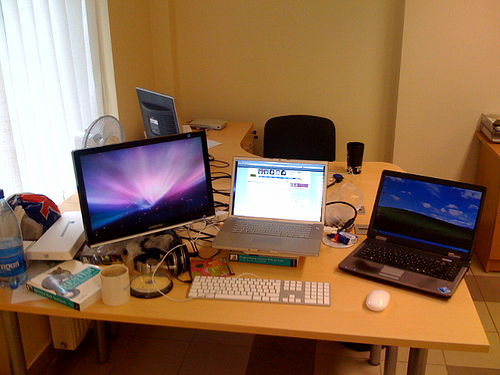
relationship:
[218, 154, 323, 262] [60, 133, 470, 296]
laptop on desk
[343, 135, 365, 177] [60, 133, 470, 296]
cup on desk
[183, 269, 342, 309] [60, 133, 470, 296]
keyboard on desk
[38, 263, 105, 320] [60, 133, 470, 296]
book on desk